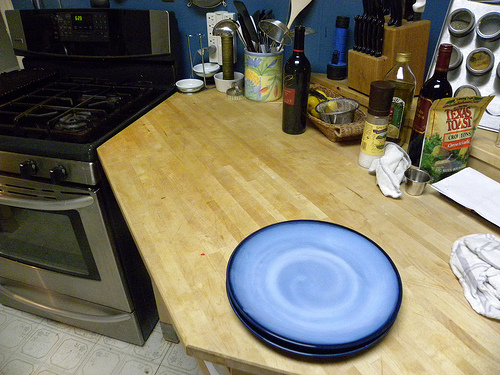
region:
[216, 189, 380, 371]
two blue plates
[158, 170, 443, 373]
light and dark blue plates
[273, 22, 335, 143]
a bottle of wine on the counter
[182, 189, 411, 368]
plates on the counter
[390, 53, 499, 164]
a bag of croutons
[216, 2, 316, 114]
a utensil holder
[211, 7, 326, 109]
utensils in a holder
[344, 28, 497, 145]
salt wine crouton oil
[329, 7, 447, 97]
block of knives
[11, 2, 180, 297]
black and silver stove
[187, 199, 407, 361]
two blue plates on counter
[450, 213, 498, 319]
hand towel on counter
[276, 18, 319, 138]
bottle of wine on counter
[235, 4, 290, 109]
flower holder for cooking utensils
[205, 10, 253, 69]
silver soup ladle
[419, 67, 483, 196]
croutons sitting on counter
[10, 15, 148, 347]
black and stainless steel stove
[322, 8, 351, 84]
flashlight next to knives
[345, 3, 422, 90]
knives in a wood block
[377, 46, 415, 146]
olive oil sitting on counter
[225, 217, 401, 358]
two dinnerware plates on a wooden counter-top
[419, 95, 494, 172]
packaged Texas toast croutons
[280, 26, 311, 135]
black bottle of red wine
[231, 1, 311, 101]
kitchen utensils in a blue and yellow ceramic holder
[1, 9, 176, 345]
stainless steel gas range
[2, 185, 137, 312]
stainless steel range's door with metal handle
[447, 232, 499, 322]
kitchen towel on top of counter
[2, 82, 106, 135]
gas burners on top of range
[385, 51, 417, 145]
virgin olive oil in a glass bottle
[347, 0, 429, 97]
wood rack containing knives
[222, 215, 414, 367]
stack of two blue plates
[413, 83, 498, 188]
yellow and green bag of crutons with red lettering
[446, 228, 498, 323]
white and grey cloth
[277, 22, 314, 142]
dark bottle of wine with rectangular red label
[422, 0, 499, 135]
grey spice rack with circular spice cannisters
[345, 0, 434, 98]
wooden knife block full of knives with black handles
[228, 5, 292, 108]
brightly colored container holding kitchen utensils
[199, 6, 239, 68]
light colored wall outlet strip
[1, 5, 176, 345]
black and stainless steel kitchen stove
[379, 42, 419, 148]
plastic bottle of olive oil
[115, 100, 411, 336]
wooden brown counter top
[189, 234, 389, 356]
blue plate on counter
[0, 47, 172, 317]
silver oven by counter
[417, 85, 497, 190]
bag by bottle of wine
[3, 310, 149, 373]
tiled floor is white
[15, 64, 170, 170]
black stove top by counter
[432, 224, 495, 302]
cloth on the table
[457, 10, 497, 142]
herbs in containers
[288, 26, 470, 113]
knifes in wooden block